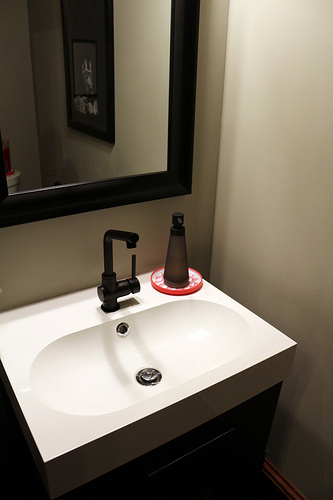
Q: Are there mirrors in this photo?
A: Yes, there is a mirror.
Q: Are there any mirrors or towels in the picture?
A: Yes, there is a mirror.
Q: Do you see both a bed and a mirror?
A: No, there is a mirror but no beds.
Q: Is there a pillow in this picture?
A: No, there are no pillows.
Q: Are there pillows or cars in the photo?
A: No, there are no pillows or cars.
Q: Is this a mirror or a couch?
A: This is a mirror.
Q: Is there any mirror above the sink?
A: Yes, there is a mirror above the sink.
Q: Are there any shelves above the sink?
A: No, there is a mirror above the sink.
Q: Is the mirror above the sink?
A: Yes, the mirror is above the sink.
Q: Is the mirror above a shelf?
A: No, the mirror is above the sink.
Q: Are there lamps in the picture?
A: No, there are no lamps.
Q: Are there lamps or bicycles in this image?
A: No, there are no lamps or bicycles.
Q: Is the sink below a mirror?
A: Yes, the sink is below a mirror.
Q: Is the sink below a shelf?
A: No, the sink is below a mirror.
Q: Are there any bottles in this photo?
A: Yes, there is a bottle.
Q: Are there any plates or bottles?
A: Yes, there is a bottle.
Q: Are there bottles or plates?
A: Yes, there is a bottle.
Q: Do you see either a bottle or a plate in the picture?
A: Yes, there is a bottle.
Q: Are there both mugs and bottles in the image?
A: No, there is a bottle but no mugs.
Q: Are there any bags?
A: No, there are no bags.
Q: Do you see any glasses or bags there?
A: No, there are no bags or glasses.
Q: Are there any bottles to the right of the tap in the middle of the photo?
A: Yes, there is a bottle to the right of the faucet.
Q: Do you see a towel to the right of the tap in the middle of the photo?
A: No, there is a bottle to the right of the faucet.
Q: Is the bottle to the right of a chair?
A: No, the bottle is to the right of the tap.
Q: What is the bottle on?
A: The bottle is on the counter.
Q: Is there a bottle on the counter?
A: Yes, there is a bottle on the counter.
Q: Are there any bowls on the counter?
A: No, there is a bottle on the counter.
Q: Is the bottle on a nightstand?
A: No, the bottle is on the counter.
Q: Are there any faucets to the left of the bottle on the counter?
A: Yes, there is a faucet to the left of the bottle.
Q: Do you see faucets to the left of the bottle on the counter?
A: Yes, there is a faucet to the left of the bottle.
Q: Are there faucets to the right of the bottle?
A: No, the faucet is to the left of the bottle.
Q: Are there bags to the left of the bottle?
A: No, there is a faucet to the left of the bottle.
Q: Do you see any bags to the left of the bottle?
A: No, there is a faucet to the left of the bottle.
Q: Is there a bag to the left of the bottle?
A: No, there is a faucet to the left of the bottle.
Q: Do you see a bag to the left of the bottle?
A: No, there is a faucet to the left of the bottle.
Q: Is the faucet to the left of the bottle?
A: Yes, the faucet is to the left of the bottle.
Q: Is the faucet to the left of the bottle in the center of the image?
A: Yes, the faucet is to the left of the bottle.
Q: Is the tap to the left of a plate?
A: No, the tap is to the left of the bottle.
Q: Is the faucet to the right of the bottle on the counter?
A: No, the faucet is to the left of the bottle.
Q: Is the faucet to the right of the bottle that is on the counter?
A: No, the faucet is to the left of the bottle.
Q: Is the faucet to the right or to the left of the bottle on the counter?
A: The faucet is to the left of the bottle.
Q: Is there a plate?
A: No, there are no plates.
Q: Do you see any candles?
A: No, there are no candles.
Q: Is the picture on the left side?
A: Yes, the picture is on the left of the image.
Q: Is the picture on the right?
A: No, the picture is on the left of the image.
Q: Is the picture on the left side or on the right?
A: The picture is on the left of the image.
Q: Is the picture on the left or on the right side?
A: The picture is on the left of the image.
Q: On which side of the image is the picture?
A: The picture is on the left of the image.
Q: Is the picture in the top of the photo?
A: Yes, the picture is in the top of the image.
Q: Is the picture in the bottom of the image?
A: No, the picture is in the top of the image.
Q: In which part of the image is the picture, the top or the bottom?
A: The picture is in the top of the image.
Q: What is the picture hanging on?
A: The picture is hanging on the wall.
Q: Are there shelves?
A: No, there are no shelves.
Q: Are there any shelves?
A: No, there are no shelves.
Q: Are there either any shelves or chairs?
A: No, there are no shelves or chairs.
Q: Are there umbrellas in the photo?
A: No, there are no umbrellas.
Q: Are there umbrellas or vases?
A: No, there are no umbrellas or vases.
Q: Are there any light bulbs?
A: No, there are no light bulbs.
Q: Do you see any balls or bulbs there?
A: No, there are no bulbs or balls.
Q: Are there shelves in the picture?
A: No, there are no shelves.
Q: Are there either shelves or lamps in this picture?
A: No, there are no shelves or lamps.